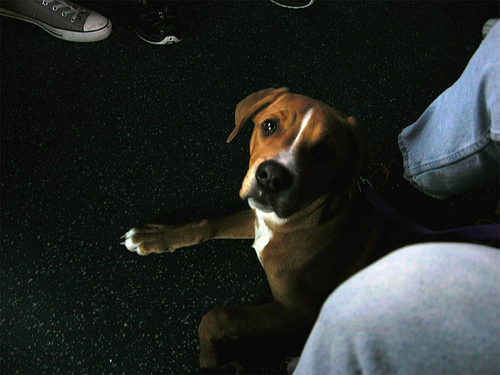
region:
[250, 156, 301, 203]
the dog has a black nose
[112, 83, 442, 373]
the dog is white and brown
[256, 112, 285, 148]
the dog has black eyes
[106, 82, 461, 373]
the dog is lying on the ground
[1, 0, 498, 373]
the ground is concrete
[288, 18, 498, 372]
the man is wearing jeans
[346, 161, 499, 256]
the dog is on a leash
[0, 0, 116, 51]
the tennis shoes are grey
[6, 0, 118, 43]
the tennis shoes have white laces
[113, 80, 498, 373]
the dog is looking up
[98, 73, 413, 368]
dog on the floor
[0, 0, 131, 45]
grey and white shoe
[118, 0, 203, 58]
black and white shoe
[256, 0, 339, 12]
black and white shoe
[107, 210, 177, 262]
brown and white dog paw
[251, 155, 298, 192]
black nose of a dog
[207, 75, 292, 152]
brown ear of a dog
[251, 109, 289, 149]
eye of a dog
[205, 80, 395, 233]
head of a dog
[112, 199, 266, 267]
front leg and paw of a dog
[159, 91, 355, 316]
brown dog on floor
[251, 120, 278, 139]
right eye of dog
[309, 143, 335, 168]
left eye of dog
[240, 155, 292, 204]
black nose of dog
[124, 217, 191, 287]
right paw of dog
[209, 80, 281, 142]
right ear of dog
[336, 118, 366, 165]
left ear of dog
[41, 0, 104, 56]
grey converse shoe on person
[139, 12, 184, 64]
black athletic shoe on person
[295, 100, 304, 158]
white marking on dog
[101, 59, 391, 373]
brown dog looking at camera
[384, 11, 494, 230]
blue jeans on a person's leg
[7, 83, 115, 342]
speckled floor where dog lies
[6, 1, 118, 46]
grey converse sneaker on a person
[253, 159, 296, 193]
nose of a dog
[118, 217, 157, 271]
front right paw of a dog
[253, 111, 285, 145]
right eye of a dog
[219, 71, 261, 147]
right ear of a dog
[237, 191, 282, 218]
mouth of a dog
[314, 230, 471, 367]
knee of a man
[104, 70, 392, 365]
dog laying on floor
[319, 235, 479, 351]
knee in blue jean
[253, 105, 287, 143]
eye on dog's head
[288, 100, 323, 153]
white stripe on head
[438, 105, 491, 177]
seam on blue jeans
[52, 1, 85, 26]
shoe laces on sneaker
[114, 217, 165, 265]
paw with white toes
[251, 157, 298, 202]
black nose on dog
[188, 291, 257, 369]
bent leg of dog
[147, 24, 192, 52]
white tip of sneaker